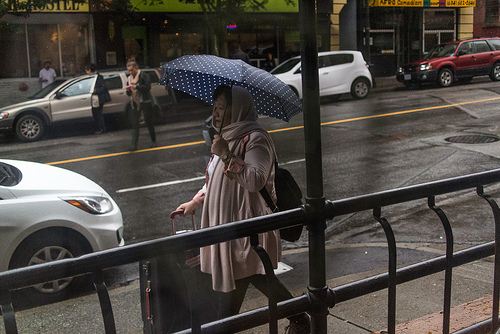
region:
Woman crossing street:
[115, 50, 170, 150]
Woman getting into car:
[76, 61, 115, 127]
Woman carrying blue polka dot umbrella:
[161, 89, 313, 332]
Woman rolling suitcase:
[178, 85, 309, 332]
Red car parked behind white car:
[391, 34, 498, 90]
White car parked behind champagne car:
[270, 47, 374, 99]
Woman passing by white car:
[0, 150, 131, 291]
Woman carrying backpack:
[172, 85, 309, 332]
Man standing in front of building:
[36, 55, 57, 95]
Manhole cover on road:
[441, 128, 498, 144]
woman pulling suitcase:
[136, 51, 304, 332]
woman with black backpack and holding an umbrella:
[140, 52, 312, 332]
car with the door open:
[0, 65, 180, 142]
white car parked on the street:
[268, 50, 374, 103]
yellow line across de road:
[35, 95, 499, 165]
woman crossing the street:
[118, 57, 159, 152]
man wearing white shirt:
[38, 57, 55, 94]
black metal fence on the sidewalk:
[0, 169, 499, 332]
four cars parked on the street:
[0, 34, 498, 302]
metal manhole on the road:
[440, 133, 499, 145]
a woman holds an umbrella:
[132, 45, 336, 330]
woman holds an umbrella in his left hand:
[142, 45, 313, 183]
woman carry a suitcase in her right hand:
[115, 87, 305, 329]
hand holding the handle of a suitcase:
[151, 198, 203, 237]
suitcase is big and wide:
[129, 203, 259, 331]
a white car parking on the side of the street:
[273, 45, 373, 112]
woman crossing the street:
[111, 53, 168, 168]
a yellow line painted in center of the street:
[321, 88, 486, 140]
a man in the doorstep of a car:
[13, 60, 118, 127]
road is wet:
[338, 90, 495, 217]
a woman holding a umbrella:
[158, 47, 299, 279]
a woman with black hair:
[203, 77, 262, 142]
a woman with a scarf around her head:
[205, 90, 262, 140]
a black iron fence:
[96, 170, 473, 332]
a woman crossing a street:
[85, 50, 155, 152]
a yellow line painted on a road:
[332, 98, 473, 141]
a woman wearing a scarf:
[116, 60, 158, 122]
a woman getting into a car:
[46, 57, 120, 132]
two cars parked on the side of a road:
[276, 40, 492, 100]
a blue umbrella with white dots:
[171, 55, 294, 107]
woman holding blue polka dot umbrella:
[151, 32, 331, 332]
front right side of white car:
[6, 146, 125, 301]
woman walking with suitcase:
[133, 85, 300, 332]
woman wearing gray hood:
[182, 85, 279, 306]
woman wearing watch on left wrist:
[193, 85, 273, 192]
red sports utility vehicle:
[397, 31, 499, 86]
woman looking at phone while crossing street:
[116, 55, 168, 237]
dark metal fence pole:
[286, 1, 349, 333]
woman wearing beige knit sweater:
[135, 36, 309, 330]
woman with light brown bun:
[123, 51, 158, 153]